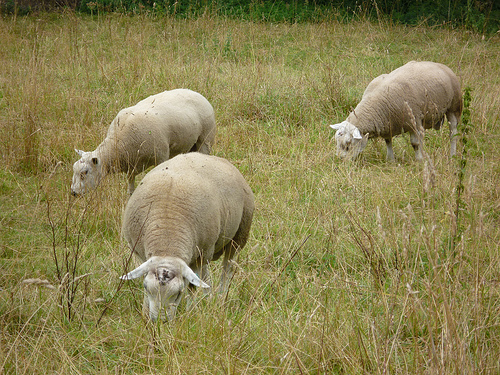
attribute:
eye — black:
[341, 139, 350, 151]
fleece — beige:
[142, 172, 206, 244]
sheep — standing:
[119, 152, 256, 324]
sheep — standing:
[103, 133, 262, 310]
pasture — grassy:
[32, 12, 472, 348]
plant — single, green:
[450, 82, 472, 264]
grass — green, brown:
[281, 173, 493, 343]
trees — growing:
[204, 4, 365, 52]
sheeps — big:
[41, 37, 482, 314]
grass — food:
[0, 1, 498, 373]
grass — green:
[367, 196, 450, 283]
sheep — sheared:
[331, 59, 466, 168]